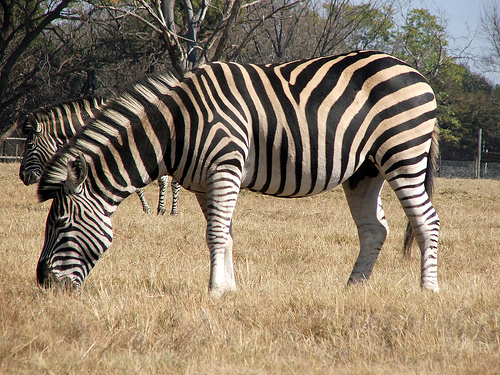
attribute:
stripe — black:
[253, 57, 307, 197]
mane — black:
[35, 65, 187, 202]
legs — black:
[370, 137, 442, 295]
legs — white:
[332, 161, 391, 286]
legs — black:
[200, 165, 242, 297]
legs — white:
[152, 171, 172, 215]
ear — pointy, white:
[46, 137, 96, 181]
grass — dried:
[5, 275, 498, 374]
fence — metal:
[431, 160, 498, 182]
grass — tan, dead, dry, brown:
[0, 161, 499, 373]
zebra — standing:
[34, 47, 443, 300]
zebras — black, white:
[31, 46, 460, 303]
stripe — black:
[252, 61, 322, 197]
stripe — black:
[258, 62, 317, 206]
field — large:
[4, 146, 484, 365]